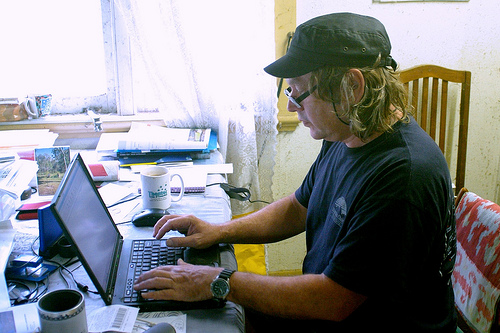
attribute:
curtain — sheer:
[134, 6, 279, 170]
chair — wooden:
[397, 65, 472, 196]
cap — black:
[263, 12, 395, 77]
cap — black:
[251, 9, 417, 100]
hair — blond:
[257, 11, 422, 126]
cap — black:
[263, 12, 425, 79]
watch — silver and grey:
[209, 261, 258, 297]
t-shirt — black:
[287, 119, 462, 331]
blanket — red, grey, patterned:
[456, 192, 498, 329]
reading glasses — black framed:
[278, 84, 323, 106]